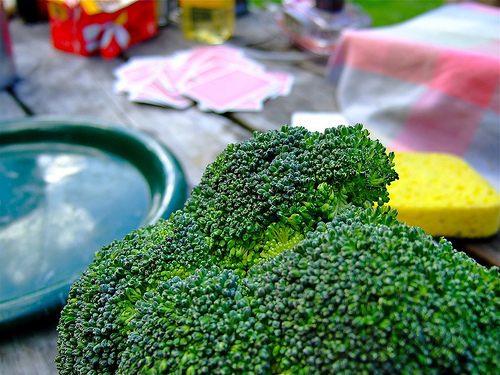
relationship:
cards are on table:
[111, 44, 296, 114] [3, 3, 498, 375]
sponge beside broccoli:
[379, 145, 499, 241] [58, 127, 499, 374]